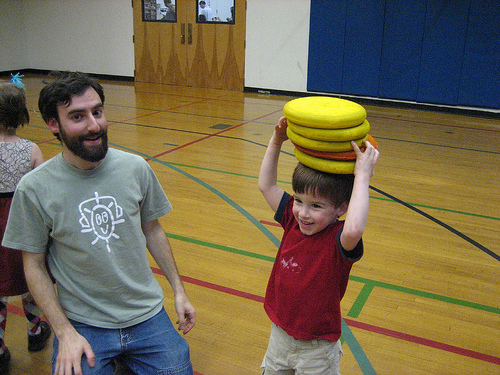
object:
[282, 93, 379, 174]
frisbees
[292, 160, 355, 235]
head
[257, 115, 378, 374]
boy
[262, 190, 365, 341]
shirt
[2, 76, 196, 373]
man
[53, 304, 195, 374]
jeans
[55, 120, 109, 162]
beard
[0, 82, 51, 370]
girl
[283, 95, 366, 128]
frisbee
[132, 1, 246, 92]
doors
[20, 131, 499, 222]
line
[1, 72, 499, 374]
floor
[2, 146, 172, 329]
shirt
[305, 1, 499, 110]
padding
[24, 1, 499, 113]
wall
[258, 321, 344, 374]
pants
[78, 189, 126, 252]
image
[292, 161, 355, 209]
hair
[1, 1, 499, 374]
gymnasium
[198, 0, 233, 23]
people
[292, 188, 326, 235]
face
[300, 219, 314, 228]
smile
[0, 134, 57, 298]
dress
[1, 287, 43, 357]
tights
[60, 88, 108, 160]
face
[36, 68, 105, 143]
hair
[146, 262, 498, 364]
line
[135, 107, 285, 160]
line